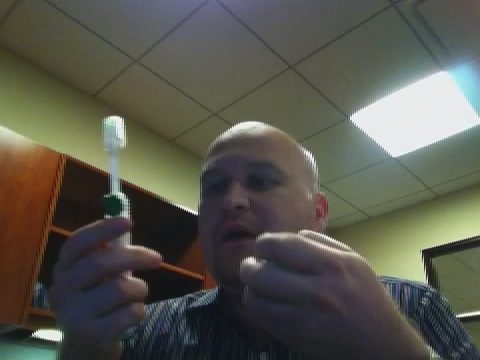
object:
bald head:
[202, 121, 315, 169]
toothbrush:
[100, 114, 132, 279]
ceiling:
[1, 0, 475, 231]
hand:
[47, 214, 162, 360]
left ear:
[309, 192, 328, 231]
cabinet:
[1, 123, 217, 329]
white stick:
[100, 113, 138, 341]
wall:
[328, 184, 478, 286]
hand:
[236, 228, 445, 358]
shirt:
[92, 274, 476, 358]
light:
[349, 64, 480, 160]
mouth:
[219, 222, 258, 245]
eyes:
[249, 175, 277, 188]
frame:
[419, 233, 478, 294]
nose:
[220, 176, 251, 210]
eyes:
[205, 180, 228, 191]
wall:
[0, 45, 219, 230]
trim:
[206, 0, 298, 75]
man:
[44, 119, 477, 360]